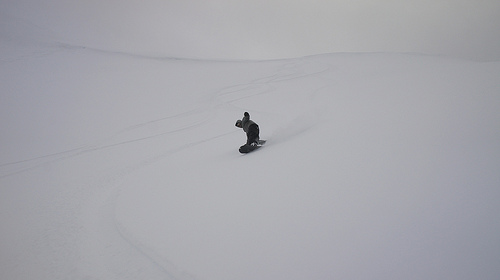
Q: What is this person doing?
A: Snowboarding.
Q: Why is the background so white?
A: Snow is everywhere.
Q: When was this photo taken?
A: During the daytime.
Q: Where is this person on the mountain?
A: Heading down it.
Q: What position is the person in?
A: Standing up.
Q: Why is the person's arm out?
A: For balance.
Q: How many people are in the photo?
A: One.